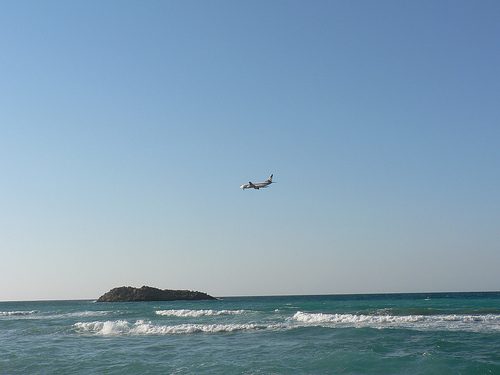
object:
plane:
[240, 173, 276, 190]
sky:
[0, 0, 499, 301]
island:
[95, 285, 221, 300]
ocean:
[0, 291, 500, 374]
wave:
[71, 309, 500, 338]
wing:
[248, 182, 253, 186]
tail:
[268, 174, 274, 183]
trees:
[96, 286, 218, 302]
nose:
[240, 184, 246, 188]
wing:
[267, 180, 273, 184]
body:
[242, 180, 270, 187]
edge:
[97, 287, 121, 302]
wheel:
[255, 186, 259, 189]